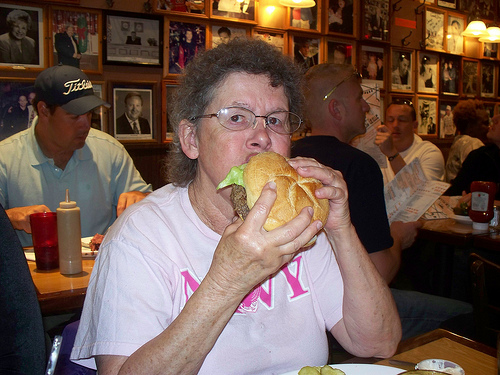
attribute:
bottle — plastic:
[41, 200, 105, 271]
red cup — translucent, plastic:
[28, 211, 59, 270]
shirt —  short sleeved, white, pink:
[66, 172, 354, 374]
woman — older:
[60, 24, 410, 374]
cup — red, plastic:
[27, 214, 58, 275]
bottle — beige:
[54, 185, 85, 277]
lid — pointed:
[56, 186, 79, 209]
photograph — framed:
[108, 75, 156, 148]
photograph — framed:
[387, 44, 414, 94]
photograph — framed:
[286, 29, 322, 74]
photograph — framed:
[46, 5, 107, 78]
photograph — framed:
[424, 6, 446, 60]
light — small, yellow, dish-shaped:
[278, 0, 319, 12]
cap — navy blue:
[23, 32, 130, 152]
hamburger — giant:
[222, 147, 335, 245]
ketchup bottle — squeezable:
[467, 180, 494, 232]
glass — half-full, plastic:
[32, 204, 57, 274]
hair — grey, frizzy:
[205, 50, 268, 130]